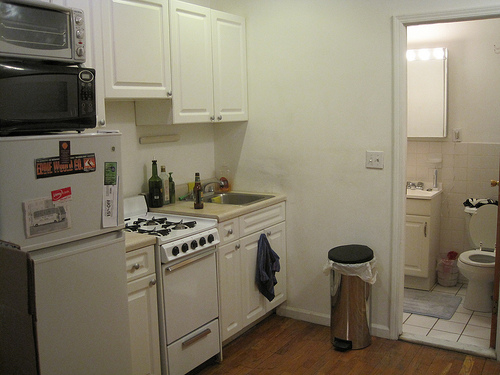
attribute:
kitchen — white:
[1, 0, 395, 374]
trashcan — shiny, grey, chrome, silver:
[327, 244, 375, 352]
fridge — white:
[1, 131, 136, 375]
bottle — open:
[150, 159, 163, 207]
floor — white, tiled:
[402, 281, 495, 358]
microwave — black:
[1, 62, 97, 136]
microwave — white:
[1, 0, 87, 68]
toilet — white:
[458, 203, 499, 313]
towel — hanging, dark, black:
[257, 234, 280, 302]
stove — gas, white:
[120, 194, 221, 374]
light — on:
[407, 48, 420, 66]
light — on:
[419, 48, 432, 62]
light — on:
[431, 47, 445, 61]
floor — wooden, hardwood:
[186, 314, 499, 374]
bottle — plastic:
[216, 169, 233, 192]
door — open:
[489, 159, 499, 350]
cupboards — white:
[102, 0, 171, 100]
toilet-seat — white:
[460, 246, 499, 269]